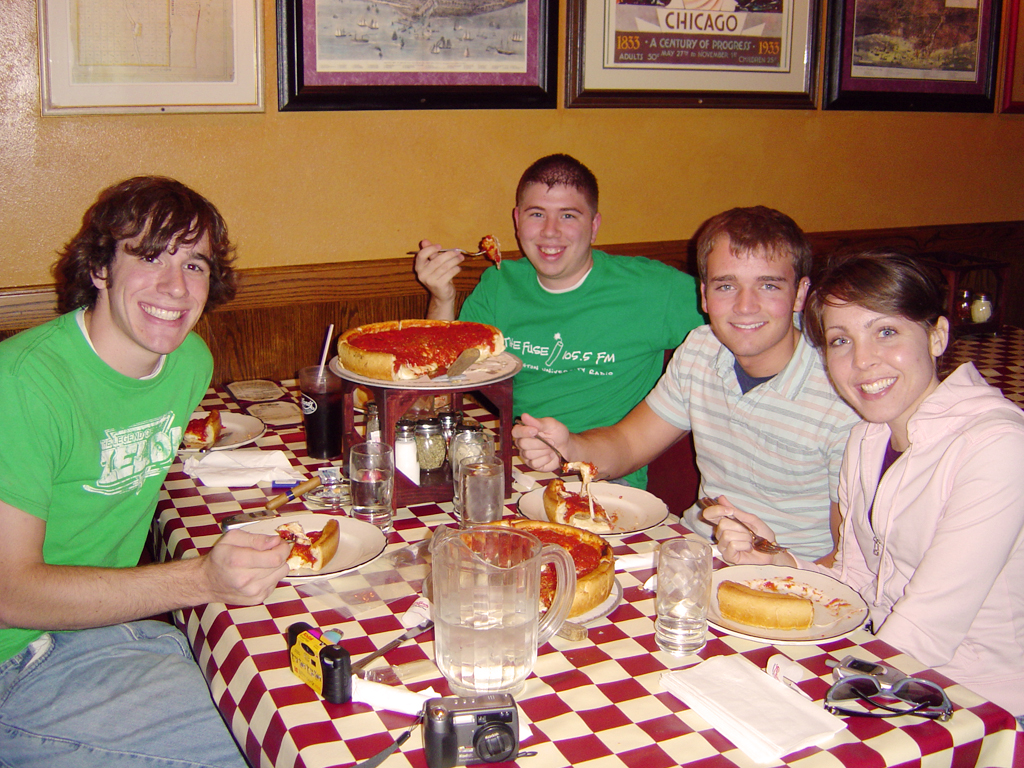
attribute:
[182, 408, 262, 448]
plate — dining